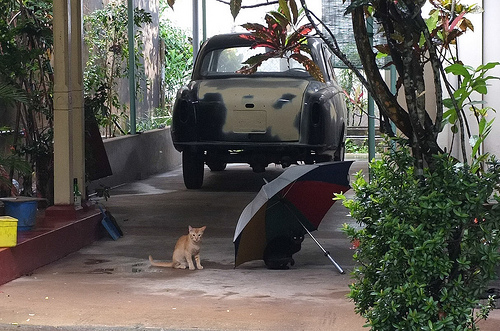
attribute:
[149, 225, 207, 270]
cat — sitting, orange, yellow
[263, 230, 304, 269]
cat — sitting, black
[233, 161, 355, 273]
umbrella — open, red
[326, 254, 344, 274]
handle — silver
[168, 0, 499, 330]
plant — green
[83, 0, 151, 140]
plant — green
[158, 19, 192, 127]
plant — green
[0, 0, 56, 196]
plant — green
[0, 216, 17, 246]
container — yellow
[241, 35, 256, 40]
spot — pink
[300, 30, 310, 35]
spot — pink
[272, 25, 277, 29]
spot — pink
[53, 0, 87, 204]
post — white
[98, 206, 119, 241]
shovel — broken, blue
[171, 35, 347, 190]
car — old, beat up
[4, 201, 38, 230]
bucket — blue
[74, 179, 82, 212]
fluid — green